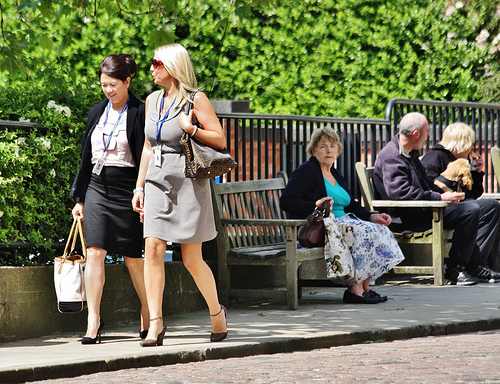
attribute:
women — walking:
[74, 54, 233, 332]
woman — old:
[285, 132, 393, 270]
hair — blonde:
[166, 44, 204, 79]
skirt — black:
[83, 174, 140, 243]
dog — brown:
[442, 157, 475, 190]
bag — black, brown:
[303, 210, 332, 242]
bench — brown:
[212, 170, 285, 259]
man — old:
[375, 107, 433, 194]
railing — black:
[221, 102, 305, 172]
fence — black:
[415, 96, 496, 117]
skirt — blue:
[344, 219, 398, 273]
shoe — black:
[144, 321, 170, 352]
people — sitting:
[382, 115, 489, 219]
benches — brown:
[233, 180, 433, 273]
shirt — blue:
[327, 176, 356, 212]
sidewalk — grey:
[256, 304, 405, 357]